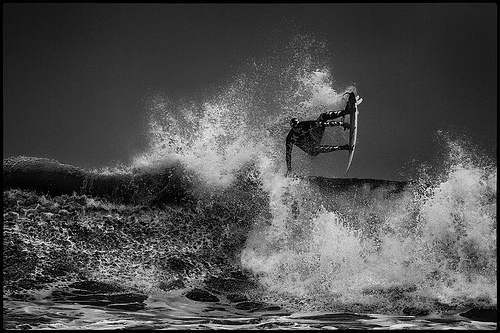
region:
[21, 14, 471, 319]
a surfer on the waves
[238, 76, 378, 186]
the surfer is flying through the air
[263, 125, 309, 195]
his arm is extended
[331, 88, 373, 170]
he is staying connected with his surfboard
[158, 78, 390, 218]
this is a wild wave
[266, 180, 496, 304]
the waves are rugged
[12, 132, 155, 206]
the crest of the wave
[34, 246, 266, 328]
this wave is agitated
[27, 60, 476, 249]
rugged water on the ocean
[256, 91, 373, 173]
this surfer is wearing a wet suit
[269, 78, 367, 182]
a person riding a surfboard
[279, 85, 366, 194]
a person doing a trick on a surboard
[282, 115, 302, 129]
a person wearing a helmet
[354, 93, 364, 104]
the fins on a surfboard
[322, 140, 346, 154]
the leg of a person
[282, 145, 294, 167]
the arm of a person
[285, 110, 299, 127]
the head of a person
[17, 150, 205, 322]
a wave in the ocean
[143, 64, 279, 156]
the splash of an ocean wave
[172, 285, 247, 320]
the foam of churned up ocean water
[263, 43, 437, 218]
a man in air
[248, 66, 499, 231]
a person in air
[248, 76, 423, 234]
a man above water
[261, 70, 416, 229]
a person above water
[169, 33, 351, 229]
a rise of water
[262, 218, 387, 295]
disturbance in the water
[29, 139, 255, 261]
a fast flow of water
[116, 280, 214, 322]
riddles in the water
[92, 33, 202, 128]
a beautiful view of sky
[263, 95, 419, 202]
a man with skating board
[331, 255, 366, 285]
part of a splash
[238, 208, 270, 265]
part of a water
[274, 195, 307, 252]
part of a splasj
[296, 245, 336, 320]
part of a splash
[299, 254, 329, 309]
par tof a water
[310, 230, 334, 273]
part of a dsplas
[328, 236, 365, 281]
part of a sp;lash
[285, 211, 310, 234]
part of a splash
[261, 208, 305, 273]
aprt of a splash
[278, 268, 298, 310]
part of a splasj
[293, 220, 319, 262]
part of a splasg